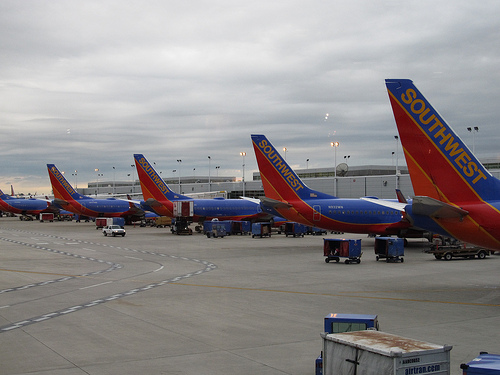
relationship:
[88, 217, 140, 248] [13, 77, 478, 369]
car driving at airport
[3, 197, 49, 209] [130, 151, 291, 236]
wing on airplane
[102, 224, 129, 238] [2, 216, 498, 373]
car driving on ground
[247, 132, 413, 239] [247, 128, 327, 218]
airplane has wing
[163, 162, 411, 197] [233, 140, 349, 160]
building has lights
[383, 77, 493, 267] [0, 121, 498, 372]
airplane at airport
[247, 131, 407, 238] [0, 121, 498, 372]
airplane at airport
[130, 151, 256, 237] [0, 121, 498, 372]
airplane at airport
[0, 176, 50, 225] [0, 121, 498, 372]
airplane at airport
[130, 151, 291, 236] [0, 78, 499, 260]
airplane are in row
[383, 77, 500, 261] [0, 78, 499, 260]
airplane in row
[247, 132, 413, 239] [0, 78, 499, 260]
airplane in row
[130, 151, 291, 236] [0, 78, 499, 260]
airplane in row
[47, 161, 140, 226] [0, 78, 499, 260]
plane in row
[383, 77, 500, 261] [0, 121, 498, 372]
airplane parked at airport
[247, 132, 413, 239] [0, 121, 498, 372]
airplane parked at airport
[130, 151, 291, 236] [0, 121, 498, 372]
airplane parked at airport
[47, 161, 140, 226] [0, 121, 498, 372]
plane parked at airport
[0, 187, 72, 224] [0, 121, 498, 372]
airplane parked at airport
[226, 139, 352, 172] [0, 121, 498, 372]
light posts are at airport